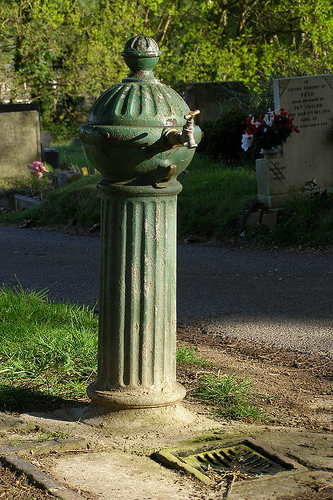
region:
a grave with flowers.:
[234, 97, 300, 228]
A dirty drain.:
[154, 428, 296, 489]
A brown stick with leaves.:
[215, 462, 250, 492]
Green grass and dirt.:
[21, 342, 78, 386]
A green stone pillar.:
[83, 351, 202, 419]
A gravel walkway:
[2, 203, 330, 376]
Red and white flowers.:
[229, 100, 313, 166]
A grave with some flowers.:
[229, 63, 332, 222]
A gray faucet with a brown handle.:
[160, 95, 224, 161]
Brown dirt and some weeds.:
[202, 345, 310, 422]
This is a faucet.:
[155, 100, 228, 158]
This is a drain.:
[145, 421, 303, 490]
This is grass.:
[205, 379, 268, 425]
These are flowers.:
[232, 102, 295, 159]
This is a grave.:
[211, 58, 331, 209]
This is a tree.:
[0, 0, 82, 135]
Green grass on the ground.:
[195, 372, 259, 427]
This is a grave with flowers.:
[234, 102, 300, 218]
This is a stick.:
[210, 463, 258, 496]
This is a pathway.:
[22, 214, 317, 360]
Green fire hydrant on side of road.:
[71, 30, 210, 436]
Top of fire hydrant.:
[76, 31, 216, 186]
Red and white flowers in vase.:
[231, 104, 302, 161]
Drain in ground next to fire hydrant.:
[151, 434, 311, 492]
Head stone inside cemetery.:
[254, 65, 331, 230]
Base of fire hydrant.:
[81, 377, 195, 431]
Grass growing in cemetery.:
[4, 293, 82, 381]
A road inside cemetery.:
[190, 238, 331, 359]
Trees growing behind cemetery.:
[193, 5, 331, 74]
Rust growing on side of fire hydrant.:
[123, 198, 171, 372]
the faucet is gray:
[172, 113, 209, 158]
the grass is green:
[15, 300, 102, 351]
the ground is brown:
[223, 341, 295, 397]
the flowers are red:
[242, 115, 269, 150]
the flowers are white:
[238, 132, 256, 157]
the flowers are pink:
[25, 155, 60, 188]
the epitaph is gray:
[278, 80, 328, 152]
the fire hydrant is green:
[86, 82, 195, 175]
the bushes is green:
[180, 16, 295, 60]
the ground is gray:
[193, 249, 299, 307]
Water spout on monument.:
[160, 106, 203, 153]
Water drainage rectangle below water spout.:
[170, 440, 281, 480]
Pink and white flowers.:
[23, 153, 54, 189]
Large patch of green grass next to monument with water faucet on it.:
[0, 283, 99, 403]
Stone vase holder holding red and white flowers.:
[257, 148, 291, 197]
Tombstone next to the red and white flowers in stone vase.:
[279, 79, 331, 205]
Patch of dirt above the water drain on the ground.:
[185, 328, 329, 419]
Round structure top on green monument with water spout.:
[125, 28, 164, 82]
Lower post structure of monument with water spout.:
[101, 187, 193, 422]